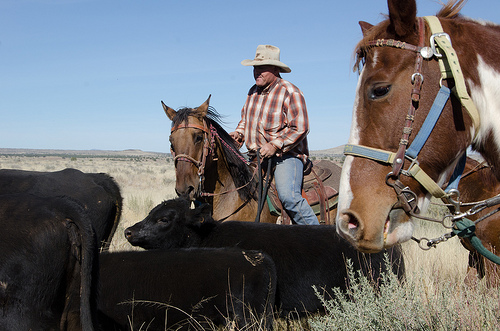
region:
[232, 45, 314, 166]
Man wearing a plaid button down shirt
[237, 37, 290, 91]
Man wearing a white cowboy hat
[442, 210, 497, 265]
Green rope attached to horse's harness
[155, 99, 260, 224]
Brown horse's black mane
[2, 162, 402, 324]
For black cattle in front of cowboy and horses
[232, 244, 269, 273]
Missing fur on calf's hind quarters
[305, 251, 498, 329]
Tall, green weeds next to brown horse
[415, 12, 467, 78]
Silver buckle on horse's harness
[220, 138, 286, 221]
Man holding horse's reins with left hand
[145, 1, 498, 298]
Three brown horses corraling cattle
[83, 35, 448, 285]
this is a rural area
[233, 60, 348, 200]
this is cattle rancher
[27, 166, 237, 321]
this is a herd of cattle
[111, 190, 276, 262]
the cow is black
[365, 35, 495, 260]
this is a horse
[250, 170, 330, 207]
this is a saddle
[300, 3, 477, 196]
the horse is brown and white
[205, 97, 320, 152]
the man has a plaid shirt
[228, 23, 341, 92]
this is a cowboy hat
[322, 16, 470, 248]
head of a horse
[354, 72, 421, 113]
eye of a horse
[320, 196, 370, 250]
nose of a horse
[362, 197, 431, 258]
mouth of a horse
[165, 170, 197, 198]
nose of a horse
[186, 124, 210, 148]
eye of a horse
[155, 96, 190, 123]
ear of a horse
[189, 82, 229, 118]
ear of a horse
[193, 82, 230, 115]
an ear of a horse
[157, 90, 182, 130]
an ear of a horse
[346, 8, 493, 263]
brown horse at the right side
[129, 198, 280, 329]
black baby cows walking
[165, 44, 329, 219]
a man riding on the horse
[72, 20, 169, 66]
blue sky in a good weather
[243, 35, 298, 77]
man wearing a hat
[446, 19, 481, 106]
horse wearing yellow straps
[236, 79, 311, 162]
his polo shirt is checkered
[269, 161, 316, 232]
cowboy's wearing blue jeans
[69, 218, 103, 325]
black tail of the cow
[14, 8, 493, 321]
A man on a horse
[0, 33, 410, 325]
The man is herding cattle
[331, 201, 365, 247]
The nose of the horse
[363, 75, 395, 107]
The eye of the horse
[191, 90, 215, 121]
The ear of the horse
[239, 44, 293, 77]
The man has on a hat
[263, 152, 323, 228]
The man is wearing jeans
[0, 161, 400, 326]
The cattle are the color black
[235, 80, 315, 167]
The man is wearing a plaid shirt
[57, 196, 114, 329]
The tail of the cow